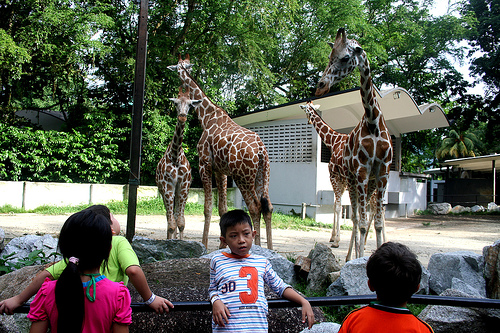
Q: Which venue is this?
A: This is a zoo.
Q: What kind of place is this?
A: It is a zoo.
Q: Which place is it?
A: It is a zoo.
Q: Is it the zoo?
A: Yes, it is the zoo.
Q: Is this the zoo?
A: Yes, it is the zoo.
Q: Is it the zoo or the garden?
A: It is the zoo.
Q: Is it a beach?
A: No, it is a zoo.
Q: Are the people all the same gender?
A: No, they are both male and female.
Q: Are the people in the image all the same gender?
A: No, they are both male and female.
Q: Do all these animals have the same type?
A: Yes, all the animals are giraffes.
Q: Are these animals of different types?
A: No, all the animals are giraffes.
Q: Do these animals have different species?
A: No, all the animals are giraffes.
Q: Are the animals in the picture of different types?
A: No, all the animals are giraffes.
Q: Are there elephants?
A: No, there are no elephants.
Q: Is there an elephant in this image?
A: No, there are no elephants.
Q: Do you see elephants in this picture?
A: No, there are no elephants.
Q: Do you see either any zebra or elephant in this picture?
A: No, there are no elephants or zebras.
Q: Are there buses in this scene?
A: No, there are no buses.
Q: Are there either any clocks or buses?
A: No, there are no buses or clocks.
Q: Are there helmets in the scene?
A: No, there are no helmets.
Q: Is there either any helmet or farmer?
A: No, there are no helmets or farmers.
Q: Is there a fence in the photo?
A: Yes, there is a fence.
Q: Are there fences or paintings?
A: Yes, there is a fence.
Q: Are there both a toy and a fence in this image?
A: No, there is a fence but no toys.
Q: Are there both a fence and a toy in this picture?
A: No, there is a fence but no toys.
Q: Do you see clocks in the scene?
A: No, there are no clocks.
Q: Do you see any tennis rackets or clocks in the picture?
A: No, there are no clocks or tennis rackets.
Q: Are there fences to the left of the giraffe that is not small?
A: Yes, there is a fence to the left of the giraffe.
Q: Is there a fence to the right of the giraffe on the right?
A: No, the fence is to the left of the giraffe.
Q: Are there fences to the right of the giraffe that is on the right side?
A: No, the fence is to the left of the giraffe.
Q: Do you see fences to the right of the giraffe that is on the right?
A: No, the fence is to the left of the giraffe.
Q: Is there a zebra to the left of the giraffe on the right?
A: No, there is a fence to the left of the giraffe.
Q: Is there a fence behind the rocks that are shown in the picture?
A: Yes, there is a fence behind the rocks.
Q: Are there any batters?
A: No, there are no batters.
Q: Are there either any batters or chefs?
A: No, there are no batters or chefs.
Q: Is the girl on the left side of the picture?
A: Yes, the girl is on the left of the image.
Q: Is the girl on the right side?
A: No, the girl is on the left of the image.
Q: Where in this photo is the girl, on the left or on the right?
A: The girl is on the left of the image.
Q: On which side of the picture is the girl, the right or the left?
A: The girl is on the left of the image.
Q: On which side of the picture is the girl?
A: The girl is on the left of the image.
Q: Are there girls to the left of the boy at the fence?
A: Yes, there is a girl to the left of the boy.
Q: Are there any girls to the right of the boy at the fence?
A: No, the girl is to the left of the boy.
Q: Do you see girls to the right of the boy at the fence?
A: No, the girl is to the left of the boy.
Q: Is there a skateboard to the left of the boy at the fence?
A: No, there is a girl to the left of the boy.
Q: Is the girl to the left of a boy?
A: Yes, the girl is to the left of a boy.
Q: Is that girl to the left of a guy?
A: No, the girl is to the left of a boy.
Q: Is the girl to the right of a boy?
A: No, the girl is to the left of a boy.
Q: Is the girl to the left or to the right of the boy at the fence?
A: The girl is to the left of the boy.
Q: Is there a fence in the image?
A: Yes, there is a fence.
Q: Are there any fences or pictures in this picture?
A: Yes, there is a fence.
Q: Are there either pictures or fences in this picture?
A: Yes, there is a fence.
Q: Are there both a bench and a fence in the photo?
A: No, there is a fence but no benches.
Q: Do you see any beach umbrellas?
A: No, there are no beach umbrellas.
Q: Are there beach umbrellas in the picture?
A: No, there are no beach umbrellas.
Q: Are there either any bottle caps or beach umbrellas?
A: No, there are no beach umbrellas or bottle caps.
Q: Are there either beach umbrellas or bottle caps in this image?
A: No, there are no beach umbrellas or bottle caps.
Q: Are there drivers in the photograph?
A: No, there are no drivers.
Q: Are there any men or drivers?
A: No, there are no drivers or men.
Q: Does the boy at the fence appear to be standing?
A: Yes, the boy is standing.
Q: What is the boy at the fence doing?
A: The boy is standing.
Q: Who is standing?
A: The boy is standing.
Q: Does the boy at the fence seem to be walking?
A: No, the boy is standing.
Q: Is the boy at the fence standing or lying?
A: The boy is standing.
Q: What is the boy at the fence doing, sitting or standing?
A: The boy is standing.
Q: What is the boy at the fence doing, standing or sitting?
A: The boy is standing.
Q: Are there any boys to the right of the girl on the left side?
A: Yes, there is a boy to the right of the girl.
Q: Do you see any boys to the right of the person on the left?
A: Yes, there is a boy to the right of the girl.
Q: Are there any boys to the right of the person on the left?
A: Yes, there is a boy to the right of the girl.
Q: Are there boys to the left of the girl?
A: No, the boy is to the right of the girl.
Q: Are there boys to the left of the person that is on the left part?
A: No, the boy is to the right of the girl.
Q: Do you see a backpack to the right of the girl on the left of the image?
A: No, there is a boy to the right of the girl.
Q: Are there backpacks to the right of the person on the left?
A: No, there is a boy to the right of the girl.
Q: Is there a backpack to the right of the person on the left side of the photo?
A: No, there is a boy to the right of the girl.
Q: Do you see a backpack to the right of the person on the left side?
A: No, there is a boy to the right of the girl.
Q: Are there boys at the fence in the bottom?
A: Yes, there is a boy at the fence.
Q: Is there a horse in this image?
A: No, there are no horses.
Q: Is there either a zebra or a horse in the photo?
A: No, there are no horses or zebras.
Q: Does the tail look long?
A: Yes, the tail is long.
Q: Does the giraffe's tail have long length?
A: Yes, the tail is long.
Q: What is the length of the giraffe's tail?
A: The tail is long.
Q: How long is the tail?
A: The tail is long.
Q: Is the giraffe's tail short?
A: No, the tail is long.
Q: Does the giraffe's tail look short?
A: No, the tail is long.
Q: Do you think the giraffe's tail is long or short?
A: The tail is long.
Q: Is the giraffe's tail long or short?
A: The tail is long.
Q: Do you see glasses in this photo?
A: No, there are no glasses.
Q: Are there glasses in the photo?
A: No, there are no glasses.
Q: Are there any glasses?
A: No, there are no glasses.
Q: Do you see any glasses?
A: No, there are no glasses.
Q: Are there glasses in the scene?
A: No, there are no glasses.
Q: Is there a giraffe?
A: Yes, there is a giraffe.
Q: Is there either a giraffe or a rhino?
A: Yes, there is a giraffe.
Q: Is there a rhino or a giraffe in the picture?
A: Yes, there is a giraffe.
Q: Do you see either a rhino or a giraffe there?
A: Yes, there is a giraffe.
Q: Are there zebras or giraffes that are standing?
A: Yes, the giraffe is standing.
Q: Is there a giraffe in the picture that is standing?
A: Yes, there is a giraffe that is standing.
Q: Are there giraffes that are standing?
A: Yes, there is a giraffe that is standing.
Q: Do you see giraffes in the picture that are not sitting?
A: Yes, there is a giraffe that is standing .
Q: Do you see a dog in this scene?
A: No, there are no dogs.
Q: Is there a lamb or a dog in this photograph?
A: No, there are no dogs or lambs.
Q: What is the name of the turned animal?
A: The animal is a giraffe.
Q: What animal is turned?
A: The animal is a giraffe.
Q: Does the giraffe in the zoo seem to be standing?
A: Yes, the giraffe is standing.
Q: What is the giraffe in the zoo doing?
A: The giraffe is standing.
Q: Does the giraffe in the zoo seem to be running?
A: No, the giraffe is standing.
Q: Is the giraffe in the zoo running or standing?
A: The giraffe is standing.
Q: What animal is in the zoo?
A: The animal is a giraffe.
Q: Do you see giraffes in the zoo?
A: Yes, there is a giraffe in the zoo.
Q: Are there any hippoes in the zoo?
A: No, there is a giraffe in the zoo.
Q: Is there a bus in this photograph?
A: No, there are no buses.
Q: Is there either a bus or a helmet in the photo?
A: No, there are no buses or helmets.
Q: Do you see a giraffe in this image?
A: Yes, there is a giraffe.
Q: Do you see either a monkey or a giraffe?
A: Yes, there is a giraffe.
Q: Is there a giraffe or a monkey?
A: Yes, there is a giraffe.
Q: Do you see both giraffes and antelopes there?
A: No, there is a giraffe but no antelopes.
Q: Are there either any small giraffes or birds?
A: Yes, there is a small giraffe.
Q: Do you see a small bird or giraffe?
A: Yes, there is a small giraffe.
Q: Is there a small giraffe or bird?
A: Yes, there is a small giraffe.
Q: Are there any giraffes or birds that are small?
A: Yes, the giraffe is small.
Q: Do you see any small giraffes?
A: Yes, there is a small giraffe.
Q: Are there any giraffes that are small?
A: Yes, there is a small giraffe.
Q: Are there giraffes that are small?
A: Yes, there is a giraffe that is small.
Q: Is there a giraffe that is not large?
A: Yes, there is a small giraffe.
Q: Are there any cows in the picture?
A: No, there are no cows.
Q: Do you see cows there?
A: No, there are no cows.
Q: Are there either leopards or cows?
A: No, there are no cows or leopards.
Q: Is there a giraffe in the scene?
A: Yes, there is a giraffe.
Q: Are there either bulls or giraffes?
A: Yes, there is a giraffe.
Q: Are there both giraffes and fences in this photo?
A: Yes, there are both a giraffe and a fence.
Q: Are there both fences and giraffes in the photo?
A: Yes, there are both a giraffe and a fence.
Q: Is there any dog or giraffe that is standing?
A: Yes, the giraffe is standing.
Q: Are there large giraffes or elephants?
A: Yes, there is a large giraffe.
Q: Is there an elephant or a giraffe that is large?
A: Yes, the giraffe is large.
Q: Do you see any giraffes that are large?
A: Yes, there is a large giraffe.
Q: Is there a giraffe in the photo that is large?
A: Yes, there is a giraffe that is large.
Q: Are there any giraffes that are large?
A: Yes, there is a giraffe that is large.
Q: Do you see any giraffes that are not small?
A: Yes, there is a large giraffe.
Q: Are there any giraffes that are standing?
A: Yes, there is a giraffe that is standing.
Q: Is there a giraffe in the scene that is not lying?
A: Yes, there is a giraffe that is standing.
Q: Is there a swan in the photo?
A: No, there are no swans.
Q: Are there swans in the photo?
A: No, there are no swans.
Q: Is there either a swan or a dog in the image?
A: No, there are no swans or dogs.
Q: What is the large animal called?
A: The animal is a giraffe.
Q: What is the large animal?
A: The animal is a giraffe.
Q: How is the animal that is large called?
A: The animal is a giraffe.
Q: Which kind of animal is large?
A: The animal is a giraffe.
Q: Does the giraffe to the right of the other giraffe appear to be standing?
A: Yes, the giraffe is standing.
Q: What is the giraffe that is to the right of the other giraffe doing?
A: The giraffe is standing.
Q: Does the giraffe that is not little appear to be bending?
A: No, the giraffe is standing.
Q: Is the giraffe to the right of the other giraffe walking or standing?
A: The giraffe is standing.